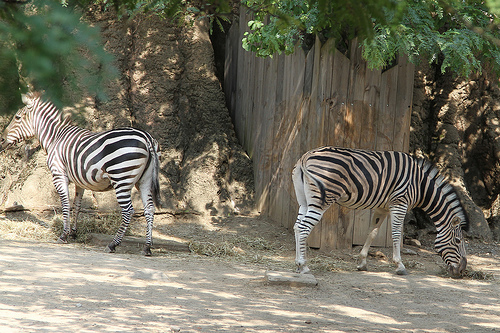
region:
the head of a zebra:
[1, 82, 61, 151]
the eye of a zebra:
[11, 102, 41, 129]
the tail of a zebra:
[134, 141, 191, 231]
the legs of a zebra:
[96, 162, 189, 262]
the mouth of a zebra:
[447, 250, 478, 287]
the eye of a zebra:
[446, 230, 471, 247]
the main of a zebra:
[424, 156, 481, 231]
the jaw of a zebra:
[426, 231, 450, 265]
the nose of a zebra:
[441, 254, 476, 281]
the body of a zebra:
[265, 112, 492, 269]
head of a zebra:
[418, 213, 483, 287]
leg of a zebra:
[377, 212, 416, 290]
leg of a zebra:
[282, 189, 337, 291]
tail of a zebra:
[153, 139, 185, 205]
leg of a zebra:
[139, 188, 179, 258]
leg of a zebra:
[106, 195, 142, 270]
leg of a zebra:
[70, 183, 95, 234]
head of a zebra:
[0, 69, 79, 169]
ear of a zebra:
[10, 82, 55, 115]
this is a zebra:
[268, 101, 498, 325]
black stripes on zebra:
[265, 105, 475, 301]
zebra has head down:
[413, 176, 483, 293]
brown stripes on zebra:
[303, 130, 368, 212]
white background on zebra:
[83, 133, 168, 185]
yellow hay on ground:
[93, 202, 373, 291]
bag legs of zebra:
[283, 200, 366, 315]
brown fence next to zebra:
[220, 45, 427, 272]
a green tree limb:
[225, 4, 487, 79]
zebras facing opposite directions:
[8, 70, 484, 297]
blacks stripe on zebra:
[118, 199, 130, 206]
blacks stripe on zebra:
[115, 193, 130, 199]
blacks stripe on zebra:
[113, 188, 130, 194]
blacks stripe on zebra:
[115, 183, 135, 190]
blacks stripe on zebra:
[103, 172, 136, 184]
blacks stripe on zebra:
[105, 163, 140, 175]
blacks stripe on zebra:
[100, 153, 145, 167]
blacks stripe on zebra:
[430, 198, 447, 223]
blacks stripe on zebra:
[303, 213, 318, 220]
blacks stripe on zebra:
[313, 194, 329, 205]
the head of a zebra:
[0, 81, 54, 147]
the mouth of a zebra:
[2, 121, 21, 148]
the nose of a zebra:
[439, 258, 485, 284]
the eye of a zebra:
[445, 232, 467, 247]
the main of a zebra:
[423, 145, 480, 239]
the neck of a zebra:
[410, 171, 455, 253]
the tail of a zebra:
[131, 140, 183, 222]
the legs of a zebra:
[96, 160, 196, 298]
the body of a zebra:
[33, 98, 157, 193]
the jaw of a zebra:
[14, 114, 52, 149]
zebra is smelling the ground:
[291, 144, 471, 285]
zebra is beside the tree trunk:
[1, 87, 162, 256]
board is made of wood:
[225, 0, 415, 248]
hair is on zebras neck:
[416, 157, 470, 230]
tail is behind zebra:
[145, 135, 164, 210]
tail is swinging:
[298, 155, 327, 205]